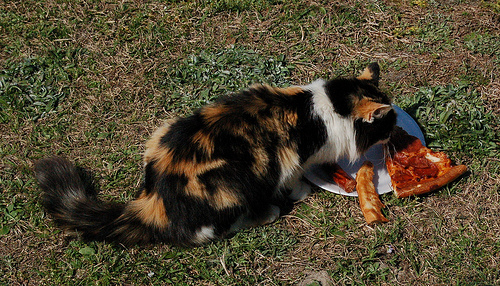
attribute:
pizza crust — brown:
[354, 158, 387, 227]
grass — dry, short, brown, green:
[1, 0, 498, 284]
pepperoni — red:
[390, 170, 414, 186]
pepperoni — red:
[409, 154, 439, 180]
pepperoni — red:
[395, 131, 422, 155]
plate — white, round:
[302, 106, 426, 198]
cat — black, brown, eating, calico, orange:
[33, 55, 397, 248]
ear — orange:
[356, 96, 392, 124]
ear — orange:
[356, 61, 381, 87]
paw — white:
[284, 176, 312, 206]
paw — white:
[243, 201, 282, 229]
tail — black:
[29, 153, 166, 243]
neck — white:
[304, 77, 357, 176]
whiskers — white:
[373, 137, 400, 172]